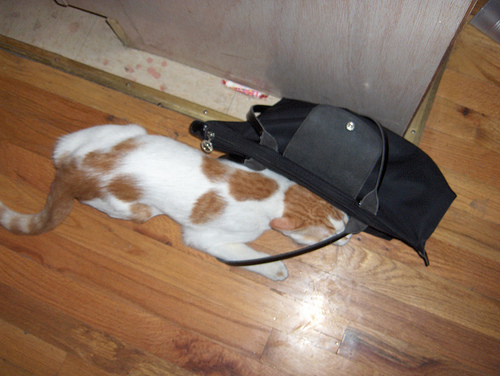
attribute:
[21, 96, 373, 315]
cat — resting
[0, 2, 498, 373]
flooring — wood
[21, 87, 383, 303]
cat — brown, white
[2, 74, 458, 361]
cat — red, white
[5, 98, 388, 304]
cat — sleeping, relaxing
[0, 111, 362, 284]
cat — white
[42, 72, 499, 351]
floor — tile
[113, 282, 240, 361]
floor — wooden